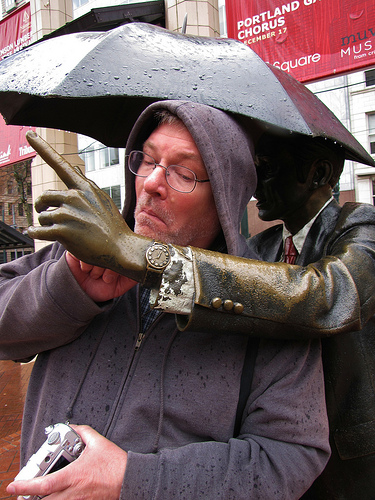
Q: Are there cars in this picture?
A: No, there are no cars.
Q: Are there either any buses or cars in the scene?
A: No, there are no cars or buses.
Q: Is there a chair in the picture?
A: No, there are no chairs.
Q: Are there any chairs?
A: No, there are no chairs.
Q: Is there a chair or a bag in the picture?
A: No, there are no chairs or bags.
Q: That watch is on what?
A: The watch is on the statue.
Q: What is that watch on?
A: The watch is on the statue.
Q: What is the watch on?
A: The watch is on the statue.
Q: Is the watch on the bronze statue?
A: Yes, the watch is on the statue.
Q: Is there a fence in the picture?
A: No, there are no fences.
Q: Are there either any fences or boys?
A: No, there are no fences or boys.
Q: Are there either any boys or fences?
A: No, there are no fences or boys.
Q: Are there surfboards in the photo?
A: No, there are no surfboards.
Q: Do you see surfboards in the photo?
A: No, there are no surfboards.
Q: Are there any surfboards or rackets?
A: No, there are no surfboards or rackets.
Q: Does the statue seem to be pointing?
A: Yes, the statue is pointing.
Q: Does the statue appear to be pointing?
A: Yes, the statue is pointing.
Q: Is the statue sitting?
A: No, the statue is pointing.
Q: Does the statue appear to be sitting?
A: No, the statue is pointing.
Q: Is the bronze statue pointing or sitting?
A: The statue is pointing.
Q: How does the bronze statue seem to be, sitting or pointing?
A: The statue is pointing.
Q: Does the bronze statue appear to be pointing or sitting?
A: The statue is pointing.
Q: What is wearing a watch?
A: The statue is wearing a watch.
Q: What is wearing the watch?
A: The statue is wearing a watch.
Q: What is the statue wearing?
A: The statue is wearing a watch.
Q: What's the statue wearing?
A: The statue is wearing a watch.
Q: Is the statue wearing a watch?
A: Yes, the statue is wearing a watch.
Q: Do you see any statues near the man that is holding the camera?
A: Yes, there is a statue near the man.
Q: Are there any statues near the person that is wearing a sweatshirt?
A: Yes, there is a statue near the man.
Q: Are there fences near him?
A: No, there is a statue near the man.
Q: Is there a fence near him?
A: No, there is a statue near the man.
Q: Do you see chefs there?
A: No, there are no chefs.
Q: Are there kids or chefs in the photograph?
A: No, there are no chefs or kids.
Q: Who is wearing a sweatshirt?
A: The man is wearing a sweatshirt.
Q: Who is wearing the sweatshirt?
A: The man is wearing a sweatshirt.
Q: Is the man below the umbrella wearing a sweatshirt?
A: Yes, the man is wearing a sweatshirt.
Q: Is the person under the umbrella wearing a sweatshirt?
A: Yes, the man is wearing a sweatshirt.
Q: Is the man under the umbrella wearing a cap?
A: No, the man is wearing a sweatshirt.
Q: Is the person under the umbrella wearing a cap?
A: No, the man is wearing a sweatshirt.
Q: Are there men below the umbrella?
A: Yes, there is a man below the umbrella.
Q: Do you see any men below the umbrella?
A: Yes, there is a man below the umbrella.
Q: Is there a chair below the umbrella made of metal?
A: No, there is a man below the umbrella.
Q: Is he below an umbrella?
A: Yes, the man is below an umbrella.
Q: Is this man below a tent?
A: No, the man is below an umbrella.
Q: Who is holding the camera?
A: The man is holding the camera.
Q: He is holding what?
A: The man is holding the camera.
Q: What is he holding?
A: The man is holding the camera.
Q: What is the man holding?
A: The man is holding the camera.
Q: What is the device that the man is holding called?
A: The device is a camera.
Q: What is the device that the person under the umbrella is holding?
A: The device is a camera.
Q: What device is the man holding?
A: The man is holding the camera.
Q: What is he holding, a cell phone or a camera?
A: The man is holding a camera.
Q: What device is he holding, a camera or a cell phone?
A: The man is holding a camera.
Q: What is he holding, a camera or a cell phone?
A: The man is holding a camera.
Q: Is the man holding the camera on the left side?
A: Yes, the man is holding the camera.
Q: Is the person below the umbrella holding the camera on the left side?
A: Yes, the man is holding the camera.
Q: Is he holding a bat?
A: No, the man is holding the camera.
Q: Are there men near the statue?
A: Yes, there is a man near the statue.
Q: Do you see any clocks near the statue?
A: No, there is a man near the statue.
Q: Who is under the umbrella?
A: The man is under the umbrella.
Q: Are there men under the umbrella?
A: Yes, there is a man under the umbrella.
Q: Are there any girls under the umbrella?
A: No, there is a man under the umbrella.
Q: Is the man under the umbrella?
A: Yes, the man is under the umbrella.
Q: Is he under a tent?
A: No, the man is under the umbrella.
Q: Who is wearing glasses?
A: The man is wearing glasses.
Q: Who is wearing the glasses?
A: The man is wearing glasses.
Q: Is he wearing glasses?
A: Yes, the man is wearing glasses.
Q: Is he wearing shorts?
A: No, the man is wearing glasses.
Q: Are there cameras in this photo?
A: Yes, there is a camera.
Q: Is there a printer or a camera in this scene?
A: Yes, there is a camera.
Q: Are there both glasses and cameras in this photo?
A: Yes, there are both a camera and glasses.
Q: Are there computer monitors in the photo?
A: No, there are no computer monitors.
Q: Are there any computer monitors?
A: No, there are no computer monitors.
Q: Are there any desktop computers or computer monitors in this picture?
A: No, there are no computer monitors or desktop computers.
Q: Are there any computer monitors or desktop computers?
A: No, there are no computer monitors or desktop computers.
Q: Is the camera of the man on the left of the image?
A: Yes, the camera is on the left of the image.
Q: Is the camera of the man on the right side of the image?
A: No, the camera is on the left of the image.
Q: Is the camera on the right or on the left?
A: The camera is on the left of the image.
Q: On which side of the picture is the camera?
A: The camera is on the left of the image.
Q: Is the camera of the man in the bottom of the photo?
A: Yes, the camera is in the bottom of the image.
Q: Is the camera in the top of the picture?
A: No, the camera is in the bottom of the image.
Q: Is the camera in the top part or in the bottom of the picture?
A: The camera is in the bottom of the image.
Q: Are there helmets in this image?
A: No, there are no helmets.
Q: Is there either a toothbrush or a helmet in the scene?
A: No, there are no helmets or toothbrushes.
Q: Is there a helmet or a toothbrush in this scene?
A: No, there are no helmets or toothbrushes.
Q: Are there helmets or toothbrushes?
A: No, there are no helmets or toothbrushes.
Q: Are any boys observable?
A: No, there are no boys.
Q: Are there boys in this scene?
A: No, there are no boys.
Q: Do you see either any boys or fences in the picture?
A: No, there are no boys or fences.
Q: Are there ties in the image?
A: Yes, there is a tie.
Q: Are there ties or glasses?
A: Yes, there is a tie.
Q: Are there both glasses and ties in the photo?
A: Yes, there are both a tie and glasses.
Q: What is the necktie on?
A: The necktie is on the statue.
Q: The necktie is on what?
A: The necktie is on the statue.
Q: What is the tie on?
A: The necktie is on the statue.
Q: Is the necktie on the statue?
A: Yes, the necktie is on the statue.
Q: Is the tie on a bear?
A: No, the tie is on the statue.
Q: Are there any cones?
A: No, there are no cones.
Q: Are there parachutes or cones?
A: No, there are no cones or parachutes.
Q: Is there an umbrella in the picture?
A: Yes, there is an umbrella.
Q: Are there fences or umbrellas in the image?
A: Yes, there is an umbrella.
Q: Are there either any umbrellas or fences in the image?
A: Yes, there is an umbrella.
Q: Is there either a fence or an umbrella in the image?
A: Yes, there is an umbrella.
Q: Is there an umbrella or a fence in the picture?
A: Yes, there is an umbrella.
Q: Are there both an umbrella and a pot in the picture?
A: No, there is an umbrella but no pots.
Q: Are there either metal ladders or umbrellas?
A: Yes, there is a metal umbrella.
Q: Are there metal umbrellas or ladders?
A: Yes, there is a metal umbrella.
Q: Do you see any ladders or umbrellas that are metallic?
A: Yes, the umbrella is metallic.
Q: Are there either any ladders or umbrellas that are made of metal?
A: Yes, the umbrella is made of metal.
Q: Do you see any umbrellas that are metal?
A: Yes, there is a metal umbrella.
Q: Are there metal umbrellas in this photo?
A: Yes, there is a metal umbrella.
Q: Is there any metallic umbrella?
A: Yes, there is a metal umbrella.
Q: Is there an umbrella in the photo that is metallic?
A: Yes, there is an umbrella that is metallic.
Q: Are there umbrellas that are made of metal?
A: Yes, there is an umbrella that is made of metal.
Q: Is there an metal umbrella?
A: Yes, there is an umbrella that is made of metal.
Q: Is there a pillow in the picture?
A: No, there are no pillows.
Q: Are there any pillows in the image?
A: No, there are no pillows.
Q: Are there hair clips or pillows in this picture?
A: No, there are no pillows or hair clips.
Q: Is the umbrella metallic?
A: Yes, the umbrella is metallic.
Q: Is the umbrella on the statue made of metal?
A: Yes, the umbrella is made of metal.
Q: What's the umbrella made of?
A: The umbrella is made of metal.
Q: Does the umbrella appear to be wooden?
A: No, the umbrella is metallic.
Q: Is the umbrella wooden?
A: No, the umbrella is metallic.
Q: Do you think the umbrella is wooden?
A: No, the umbrella is metallic.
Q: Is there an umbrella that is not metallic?
A: No, there is an umbrella but it is metallic.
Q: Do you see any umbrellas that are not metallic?
A: No, there is an umbrella but it is metallic.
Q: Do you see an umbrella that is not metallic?
A: No, there is an umbrella but it is metallic.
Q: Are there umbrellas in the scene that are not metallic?
A: No, there is an umbrella but it is metallic.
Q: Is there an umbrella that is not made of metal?
A: No, there is an umbrella but it is made of metal.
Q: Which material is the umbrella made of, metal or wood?
A: The umbrella is made of metal.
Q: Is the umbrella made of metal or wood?
A: The umbrella is made of metal.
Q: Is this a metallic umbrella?
A: Yes, this is a metallic umbrella.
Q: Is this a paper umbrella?
A: No, this is a metallic umbrella.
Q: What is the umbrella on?
A: The umbrella is on the statue.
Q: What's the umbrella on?
A: The umbrella is on the statue.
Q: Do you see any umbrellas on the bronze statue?
A: Yes, there is an umbrella on the statue.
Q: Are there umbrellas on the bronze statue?
A: Yes, there is an umbrella on the statue.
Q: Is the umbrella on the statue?
A: Yes, the umbrella is on the statue.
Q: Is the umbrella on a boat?
A: No, the umbrella is on the statue.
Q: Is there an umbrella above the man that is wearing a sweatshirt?
A: Yes, there is an umbrella above the man.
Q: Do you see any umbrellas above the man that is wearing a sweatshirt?
A: Yes, there is an umbrella above the man.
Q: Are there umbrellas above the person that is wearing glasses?
A: Yes, there is an umbrella above the man.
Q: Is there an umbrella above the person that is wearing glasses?
A: Yes, there is an umbrella above the man.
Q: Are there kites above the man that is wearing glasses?
A: No, there is an umbrella above the man.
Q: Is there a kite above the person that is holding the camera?
A: No, there is an umbrella above the man.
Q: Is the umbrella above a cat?
A: No, the umbrella is above the man.